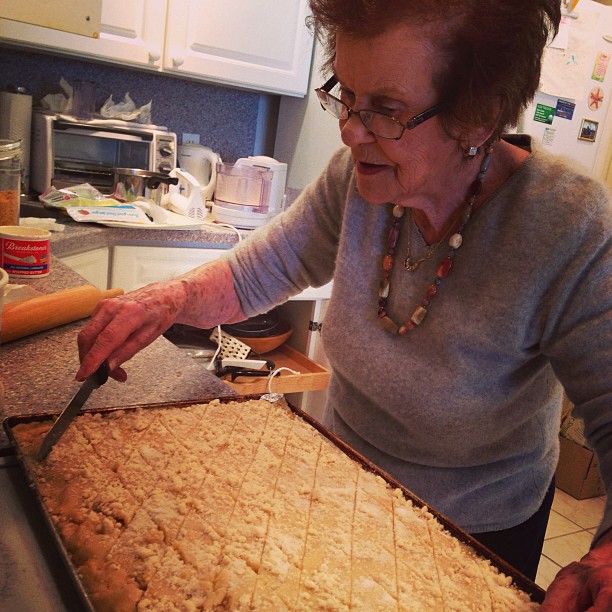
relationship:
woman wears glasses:
[75, 0, 612, 611] [312, 63, 434, 136]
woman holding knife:
[75, 0, 612, 611] [38, 362, 109, 462]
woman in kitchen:
[75, 0, 612, 611] [2, 3, 603, 609]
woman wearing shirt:
[75, 0, 612, 611] [234, 106, 610, 543]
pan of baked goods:
[2, 391, 547, 611] [12, 398, 541, 612]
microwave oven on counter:
[30, 112, 177, 195] [17, 197, 289, 277]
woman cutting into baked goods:
[75, 0, 612, 611] [12, 398, 541, 612]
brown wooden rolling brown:
[23, 306, 56, 323] [0, 284, 127, 342]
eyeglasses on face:
[315, 74, 447, 139] [293, 14, 509, 234]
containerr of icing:
[0, 211, 56, 283] [0, 217, 56, 243]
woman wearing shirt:
[273, 1, 594, 580] [211, 140, 609, 532]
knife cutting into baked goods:
[23, 358, 120, 489] [124, 418, 354, 593]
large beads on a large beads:
[358, 268, 463, 295] [379, 139, 497, 335]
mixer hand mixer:
[160, 168, 207, 219] [186, 189, 202, 200]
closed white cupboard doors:
[72, 69, 305, 99] [171, 123, 244, 143]